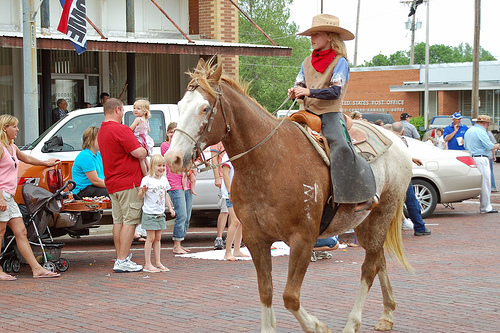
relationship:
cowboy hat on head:
[298, 13, 357, 41] [309, 30, 341, 51]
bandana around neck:
[310, 50, 338, 74] [316, 44, 334, 55]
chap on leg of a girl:
[321, 113, 378, 203] [287, 13, 377, 213]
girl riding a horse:
[287, 13, 377, 213] [164, 55, 413, 331]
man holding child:
[96, 97, 148, 273] [129, 98, 151, 174]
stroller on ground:
[0, 178, 71, 272] [3, 282, 171, 332]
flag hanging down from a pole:
[55, 1, 89, 57] [21, 1, 37, 140]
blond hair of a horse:
[387, 220, 410, 272] [164, 55, 413, 331]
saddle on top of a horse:
[290, 112, 371, 159] [164, 55, 413, 331]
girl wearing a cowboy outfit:
[287, 13, 379, 213] [295, 53, 378, 204]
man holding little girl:
[96, 97, 148, 273] [129, 98, 151, 174]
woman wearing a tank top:
[1, 112, 63, 281] [0, 146, 20, 198]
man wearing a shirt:
[463, 113, 499, 213] [462, 124, 495, 157]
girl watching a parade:
[139, 154, 179, 273] [162, 11, 420, 332]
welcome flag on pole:
[55, 1, 89, 57] [21, 1, 37, 140]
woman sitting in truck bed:
[71, 126, 108, 199] [62, 196, 112, 214]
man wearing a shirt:
[96, 97, 148, 273] [97, 120, 142, 196]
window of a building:
[110, 52, 179, 96] [1, 1, 292, 146]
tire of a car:
[414, 178, 439, 218] [412, 135, 481, 217]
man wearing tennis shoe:
[96, 97, 148, 273] [110, 258, 145, 272]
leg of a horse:
[249, 249, 275, 331] [164, 55, 413, 331]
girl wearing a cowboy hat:
[287, 13, 377, 213] [298, 13, 357, 41]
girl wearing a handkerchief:
[287, 13, 377, 213] [310, 50, 338, 74]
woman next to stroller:
[1, 112, 63, 281] [0, 178, 71, 272]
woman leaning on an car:
[1, 112, 63, 281] [16, 160, 111, 239]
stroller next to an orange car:
[0, 178, 71, 272] [16, 160, 111, 239]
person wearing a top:
[71, 126, 108, 199] [71, 148, 104, 195]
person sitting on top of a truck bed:
[71, 126, 108, 199] [62, 196, 112, 214]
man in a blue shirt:
[441, 110, 467, 150] [441, 122, 466, 150]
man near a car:
[463, 113, 499, 213] [412, 135, 481, 217]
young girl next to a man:
[139, 154, 179, 273] [96, 97, 148, 273]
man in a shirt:
[96, 97, 148, 273] [97, 120, 142, 196]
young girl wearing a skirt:
[139, 154, 179, 273] [140, 214, 168, 232]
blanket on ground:
[174, 242, 289, 263] [3, 282, 171, 332]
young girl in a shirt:
[139, 154, 179, 273] [139, 174, 172, 216]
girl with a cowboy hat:
[287, 13, 377, 213] [298, 13, 357, 41]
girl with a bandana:
[287, 13, 379, 213] [310, 50, 338, 74]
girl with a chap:
[287, 13, 379, 213] [321, 113, 378, 203]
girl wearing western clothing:
[287, 13, 379, 213] [295, 53, 378, 204]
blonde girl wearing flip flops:
[139, 154, 179, 273] [142, 266, 171, 273]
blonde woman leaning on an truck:
[1, 112, 63, 281] [16, 160, 111, 239]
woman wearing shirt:
[71, 126, 108, 199] [71, 148, 104, 195]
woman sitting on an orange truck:
[71, 126, 108, 199] [16, 159, 112, 237]